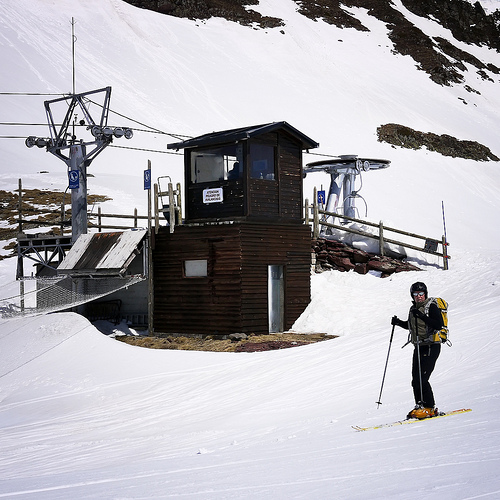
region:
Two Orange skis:
[367, 395, 489, 432]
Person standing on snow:
[366, 269, 481, 432]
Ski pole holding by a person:
[368, 309, 403, 414]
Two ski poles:
[371, 311, 429, 411]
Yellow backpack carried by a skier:
[433, 292, 457, 349]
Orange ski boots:
[406, 397, 442, 422]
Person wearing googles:
[405, 287, 435, 298]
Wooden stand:
[141, 117, 328, 348]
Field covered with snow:
[6, 341, 366, 498]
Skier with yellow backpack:
[357, 279, 477, 431]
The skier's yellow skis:
[342, 403, 475, 443]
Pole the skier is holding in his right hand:
[372, 312, 396, 417]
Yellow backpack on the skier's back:
[431, 293, 455, 346]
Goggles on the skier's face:
[409, 289, 430, 300]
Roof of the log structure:
[162, 114, 328, 155]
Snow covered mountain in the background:
[109, 1, 498, 128]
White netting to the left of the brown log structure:
[5, 272, 147, 327]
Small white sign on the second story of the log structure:
[199, 187, 227, 206]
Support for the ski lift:
[20, 91, 126, 228]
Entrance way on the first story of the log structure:
[262, 257, 292, 337]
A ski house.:
[109, 90, 338, 343]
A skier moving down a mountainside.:
[342, 270, 469, 437]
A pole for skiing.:
[354, 305, 404, 417]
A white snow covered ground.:
[137, 363, 274, 458]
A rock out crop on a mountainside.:
[380, 105, 495, 177]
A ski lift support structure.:
[18, 80, 136, 227]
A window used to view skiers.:
[234, 125, 309, 192]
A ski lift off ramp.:
[297, 170, 464, 280]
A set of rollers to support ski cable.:
[83, 119, 130, 147]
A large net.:
[7, 246, 160, 330]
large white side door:
[265, 261, 301, 343]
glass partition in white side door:
[268, 268, 285, 283]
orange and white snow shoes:
[408, 399, 442, 429]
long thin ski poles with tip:
[361, 313, 395, 421]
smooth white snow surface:
[38, 358, 266, 454]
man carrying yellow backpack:
[433, 295, 459, 359]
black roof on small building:
[170, 107, 333, 171]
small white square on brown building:
[174, 255, 217, 292]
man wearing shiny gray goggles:
[408, 289, 429, 302]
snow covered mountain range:
[165, 13, 444, 100]